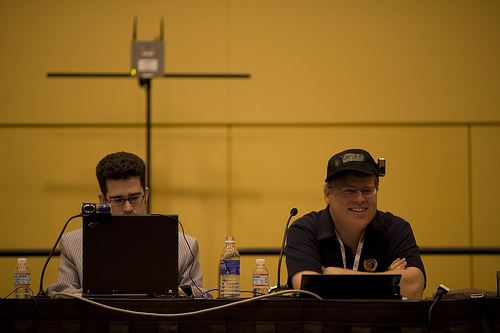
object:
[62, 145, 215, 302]
man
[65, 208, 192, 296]
computer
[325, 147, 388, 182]
hat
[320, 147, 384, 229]
head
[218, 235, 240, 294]
water bottle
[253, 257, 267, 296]
water bottle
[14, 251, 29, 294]
water bottle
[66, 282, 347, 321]
cord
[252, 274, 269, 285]
label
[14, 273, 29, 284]
label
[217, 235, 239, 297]
bottle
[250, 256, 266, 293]
bottle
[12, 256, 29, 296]
bottle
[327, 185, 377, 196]
glasses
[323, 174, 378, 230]
face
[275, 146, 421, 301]
man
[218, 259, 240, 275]
label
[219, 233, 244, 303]
water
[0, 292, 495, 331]
table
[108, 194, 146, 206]
eyeglasses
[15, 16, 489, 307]
wall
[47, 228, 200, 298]
suit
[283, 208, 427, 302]
shirt